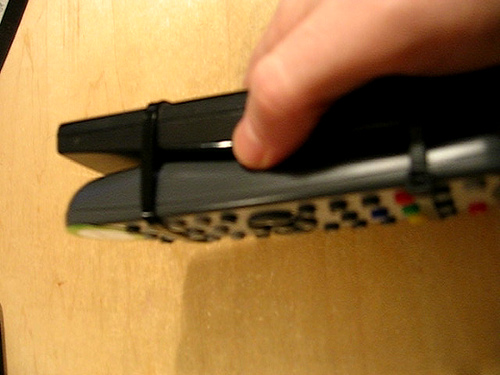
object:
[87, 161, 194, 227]
remotes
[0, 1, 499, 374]
table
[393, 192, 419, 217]
button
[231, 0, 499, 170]
hand